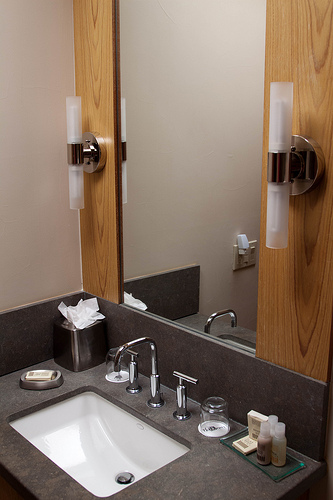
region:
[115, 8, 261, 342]
mirror above bathroom sink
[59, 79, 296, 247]
lights on either side of mirror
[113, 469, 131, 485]
silver drain in the sink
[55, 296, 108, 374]
silver tissue box on counter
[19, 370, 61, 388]
silver soap dish on the counter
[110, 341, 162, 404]
silver faucet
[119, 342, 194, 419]
silver hot and cold handles of sink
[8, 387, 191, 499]
white sink in countertop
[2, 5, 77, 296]
wall beside the sink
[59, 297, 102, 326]
white tissues hanging out of box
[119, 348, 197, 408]
Taps in the photo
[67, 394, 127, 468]
A sink in the photo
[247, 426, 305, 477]
sanitizers in the bathroom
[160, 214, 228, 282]
A mirror in the photo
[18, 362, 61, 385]
Soap in the bathroom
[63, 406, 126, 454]
White color on the sink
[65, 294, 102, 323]
Paper towel in the bathroom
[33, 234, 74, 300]
A wall in the photo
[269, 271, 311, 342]
A wooden frame in the photo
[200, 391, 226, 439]
A bottle in the photo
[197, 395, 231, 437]
water glass provided by the hotel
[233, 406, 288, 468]
toiletries provided by the hotel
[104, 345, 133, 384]
water glass provided by the hotel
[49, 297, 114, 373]
tissues in a metal container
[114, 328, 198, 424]
weird modern looking fixtures at the sink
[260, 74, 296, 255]
interesting wall sconces for the lights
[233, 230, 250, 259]
a night light in the wall socket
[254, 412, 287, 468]
liquid shampoo and conditioner provided by the hotel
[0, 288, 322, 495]
the countertop is dark marble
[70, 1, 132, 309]
wood accents next to the mirror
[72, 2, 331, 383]
mirror in wood frame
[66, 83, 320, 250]
two long lamps beside mirror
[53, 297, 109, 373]
tissue in metal box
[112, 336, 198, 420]
faucet and two handles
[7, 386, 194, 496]
sqaure white sink with drain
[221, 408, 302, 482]
toiletries on green tray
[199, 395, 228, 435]
upside down glass on counter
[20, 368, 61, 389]
soap in soap dish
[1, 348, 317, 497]
gray vanity around sink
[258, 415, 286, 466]
three bottles with white caps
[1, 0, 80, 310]
white wall of bathroom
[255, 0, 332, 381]
wood grain on board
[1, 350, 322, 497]
top of gray vanity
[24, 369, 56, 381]
soap wrapped in paper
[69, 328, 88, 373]
light reflection on tissue holder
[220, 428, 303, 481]
glass tray with green tint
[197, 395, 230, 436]
bottom of drinking glass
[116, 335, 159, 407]
light reflection on faucet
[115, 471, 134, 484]
drain in bottom of sink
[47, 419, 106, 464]
light reflection on porcelain